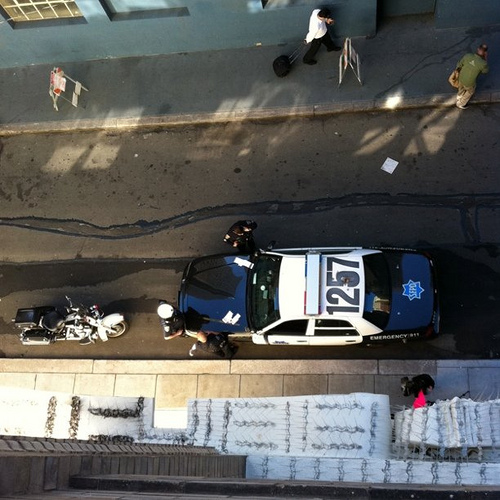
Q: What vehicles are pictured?
A: A police car and motorcycle.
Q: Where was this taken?
A: A public street.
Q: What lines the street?
A: Side walks.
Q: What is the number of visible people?
A: Five.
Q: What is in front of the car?
A: A motorcycle.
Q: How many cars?
A: One.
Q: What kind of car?
A: Police car.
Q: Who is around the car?
A: Cops.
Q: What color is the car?
A: Black and white.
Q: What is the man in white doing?
A: Pulling a black suitcase.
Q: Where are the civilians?
A: On the sidewalk.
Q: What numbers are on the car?
A: 1257.